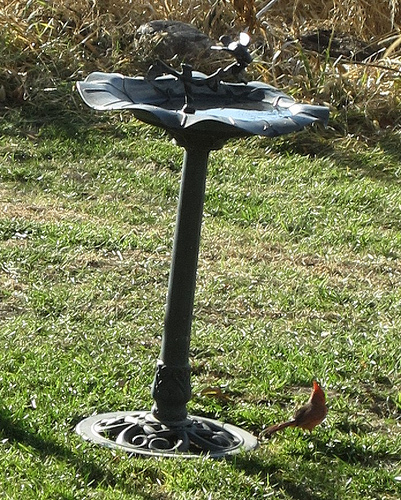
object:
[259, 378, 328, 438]
bird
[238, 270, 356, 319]
ground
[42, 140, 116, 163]
grass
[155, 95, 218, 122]
fountain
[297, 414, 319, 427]
wings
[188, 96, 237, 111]
water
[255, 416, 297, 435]
tail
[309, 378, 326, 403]
head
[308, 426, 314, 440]
legs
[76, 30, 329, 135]
bath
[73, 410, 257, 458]
base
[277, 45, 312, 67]
weeds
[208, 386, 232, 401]
leaf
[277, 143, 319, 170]
shadow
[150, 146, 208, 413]
pole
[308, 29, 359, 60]
rock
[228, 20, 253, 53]
light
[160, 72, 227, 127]
bowl